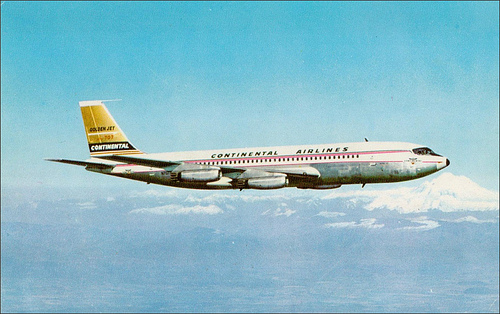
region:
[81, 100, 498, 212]
Boeing 707 in mid air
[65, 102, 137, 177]
Gold tail of airliner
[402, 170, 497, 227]
Snow covered mountain peak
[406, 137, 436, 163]
Black cockpit area of airliner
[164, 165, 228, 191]
Airliner's engine on wing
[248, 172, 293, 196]
Airliner's engine on wing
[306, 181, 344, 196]
Airliner's engine on wing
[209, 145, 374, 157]
Continental Airlines logo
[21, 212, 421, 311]
Mountainous region below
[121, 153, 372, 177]
White and red airliner cabin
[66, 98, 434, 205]
this is a jet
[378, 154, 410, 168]
the jet is white in color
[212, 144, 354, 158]
this is a writing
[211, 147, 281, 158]
the writing is in black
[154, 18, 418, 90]
this is the sky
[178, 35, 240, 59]
the sky is blue in color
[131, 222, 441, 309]
this is a mountain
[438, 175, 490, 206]
this is the snow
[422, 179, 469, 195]
the snow is white in color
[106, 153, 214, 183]
this is a wing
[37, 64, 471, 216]
a large commercial airplane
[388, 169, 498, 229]
a tall snow covered mountain peak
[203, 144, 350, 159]
Continental Airlines on the side of a plane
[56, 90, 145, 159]
a yellow or gold tail fin on the plane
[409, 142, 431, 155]
the windshield of a commercial plane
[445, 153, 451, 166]
the black nose on the plane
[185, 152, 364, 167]
a row of passenger windows along the side of the plane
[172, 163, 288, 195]
two engines on the wing of the plane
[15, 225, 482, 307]
hazy sky above the ground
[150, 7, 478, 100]
clear blue sky above the airplane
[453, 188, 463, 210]
the snow is white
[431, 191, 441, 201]
the snow is white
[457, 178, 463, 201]
the snow is white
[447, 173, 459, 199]
the snow is white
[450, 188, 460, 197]
the snow is white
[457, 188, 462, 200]
the snow is white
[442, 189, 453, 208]
the snow is white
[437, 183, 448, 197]
the snow is white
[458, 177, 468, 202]
the snow is white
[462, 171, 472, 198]
the snow is white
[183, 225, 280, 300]
the sky is cloudy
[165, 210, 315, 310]
the sky is cloudy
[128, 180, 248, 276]
the sky is cloudy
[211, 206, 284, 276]
the sky is cloudy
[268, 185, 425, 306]
the sky is cloudy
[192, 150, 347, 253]
the sky is cloudy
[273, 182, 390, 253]
the sky is cloudy